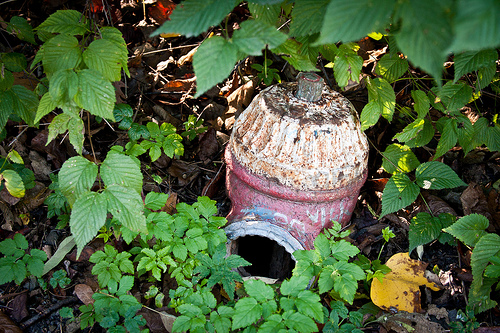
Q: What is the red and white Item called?
A: A fire hydrant.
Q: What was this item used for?
A: Putting out fires.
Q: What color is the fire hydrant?
A: Red and white.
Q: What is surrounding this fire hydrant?
A: Plants and leaves.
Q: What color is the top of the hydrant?
A: Gold.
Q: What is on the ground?
A: Leaves.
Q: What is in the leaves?
A: A fire hydrant.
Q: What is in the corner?
A: Green leaves.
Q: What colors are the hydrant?
A: Red and gold.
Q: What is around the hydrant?
A: Plants and leaves.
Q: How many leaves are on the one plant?
A: Four.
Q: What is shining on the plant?
A: The sun.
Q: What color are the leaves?
A: Green.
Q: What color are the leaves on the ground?
A: Brown.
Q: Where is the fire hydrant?
A: In the ground.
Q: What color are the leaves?
A: Green.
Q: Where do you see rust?
A: On the fire hydrant.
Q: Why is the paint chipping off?
A: It is old.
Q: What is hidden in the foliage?
A: A fire hydrant.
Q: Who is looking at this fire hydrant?
A: The photographer.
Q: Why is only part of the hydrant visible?
A: The foliage obstructs it.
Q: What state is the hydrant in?
A: Old and faded and missing parts.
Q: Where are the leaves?
A: Surrounding the hydrant.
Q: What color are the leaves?
A: Green.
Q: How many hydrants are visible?
A: One.